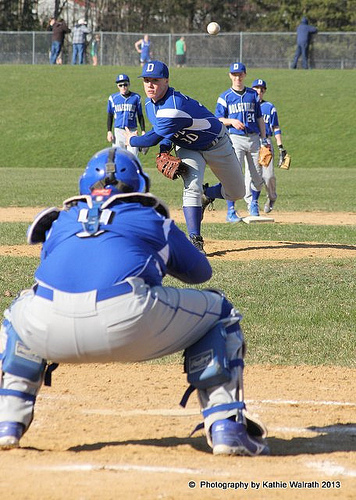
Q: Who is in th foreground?
A: A catcher.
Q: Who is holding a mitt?
A: Pitcher.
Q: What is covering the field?
A: Grass.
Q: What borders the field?
A: Fence.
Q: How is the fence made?
A: Of metal.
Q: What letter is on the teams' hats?
A: D.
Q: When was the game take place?
A: Daytime.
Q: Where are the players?
A: In the field.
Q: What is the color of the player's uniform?
A: Blue and gray.